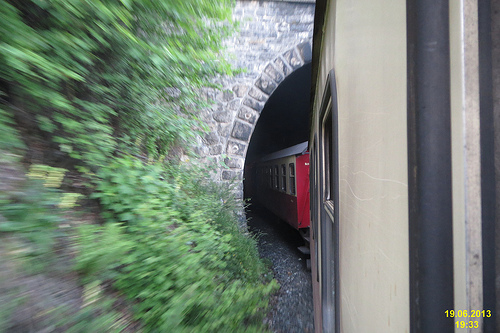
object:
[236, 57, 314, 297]
entrance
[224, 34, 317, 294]
tunnel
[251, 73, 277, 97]
stones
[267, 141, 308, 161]
top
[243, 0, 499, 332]
train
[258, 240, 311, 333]
gravel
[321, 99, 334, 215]
window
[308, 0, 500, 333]
car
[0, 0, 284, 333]
plants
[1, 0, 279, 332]
wildly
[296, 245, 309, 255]
footboard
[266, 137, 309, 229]
car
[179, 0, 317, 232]
stone wall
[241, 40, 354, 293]
tunnel mouth